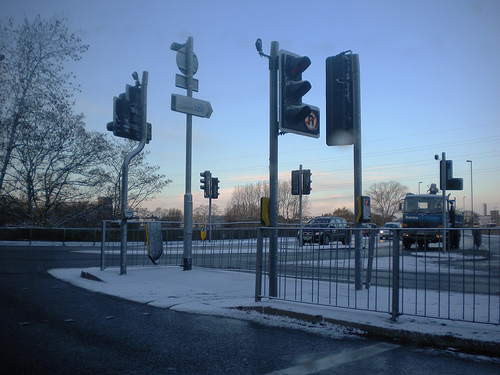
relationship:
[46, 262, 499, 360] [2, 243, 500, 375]
snow on ground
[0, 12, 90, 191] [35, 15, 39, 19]
tree has leaf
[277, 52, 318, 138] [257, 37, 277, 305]
streetlight on top of pole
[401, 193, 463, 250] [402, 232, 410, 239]
truck has light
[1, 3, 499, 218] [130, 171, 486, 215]
sky has cloud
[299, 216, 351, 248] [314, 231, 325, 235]
car has headlight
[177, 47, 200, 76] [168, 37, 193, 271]
sign on top of pole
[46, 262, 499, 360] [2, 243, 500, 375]
snow on top of ground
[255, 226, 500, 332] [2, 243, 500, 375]
railing on top of ground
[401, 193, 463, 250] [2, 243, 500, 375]
truck on top of ground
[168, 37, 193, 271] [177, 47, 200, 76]
pole has sign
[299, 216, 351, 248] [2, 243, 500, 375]
car on top of ground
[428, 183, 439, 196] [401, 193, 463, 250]
equipment on top of truck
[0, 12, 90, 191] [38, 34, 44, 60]
tree has branch